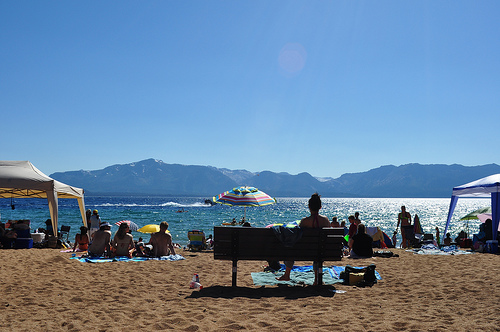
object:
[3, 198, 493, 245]
water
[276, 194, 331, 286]
woman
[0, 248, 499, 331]
beach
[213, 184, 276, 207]
beach umbrella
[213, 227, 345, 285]
bench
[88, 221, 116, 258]
people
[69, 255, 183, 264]
towel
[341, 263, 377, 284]
bag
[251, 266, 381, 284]
towel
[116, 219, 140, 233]
umbrella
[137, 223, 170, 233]
umbrella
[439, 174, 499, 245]
canopy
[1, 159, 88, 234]
canopy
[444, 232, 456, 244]
people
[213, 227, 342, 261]
back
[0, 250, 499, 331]
footprints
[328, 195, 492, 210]
sun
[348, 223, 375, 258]
woman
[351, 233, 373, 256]
shirt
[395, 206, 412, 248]
woman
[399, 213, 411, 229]
bikini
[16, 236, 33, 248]
ice chest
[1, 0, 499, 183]
sky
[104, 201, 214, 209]
wave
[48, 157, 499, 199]
mountains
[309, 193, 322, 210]
hair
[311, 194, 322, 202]
bun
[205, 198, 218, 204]
boat